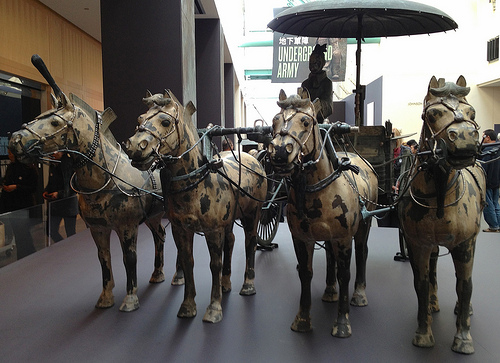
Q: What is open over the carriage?
A: An Umbrella.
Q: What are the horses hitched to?
A: Carriage.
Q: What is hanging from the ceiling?
A: A sign.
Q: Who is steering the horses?
A: The carriage driver.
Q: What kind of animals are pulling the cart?
A: Horses.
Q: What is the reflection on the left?
A: Light.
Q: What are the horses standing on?
A: A stage.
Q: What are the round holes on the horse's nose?
A: Nostrils.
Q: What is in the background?
A: An umbrella.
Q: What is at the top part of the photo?
A: Light.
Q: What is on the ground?
A: Statues of horses.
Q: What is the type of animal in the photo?
A: Horses.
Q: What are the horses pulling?
A: Carriage.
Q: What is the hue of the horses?
A: Brown.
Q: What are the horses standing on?
A: Platform.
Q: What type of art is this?
A: Statue.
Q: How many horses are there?
A: Four.